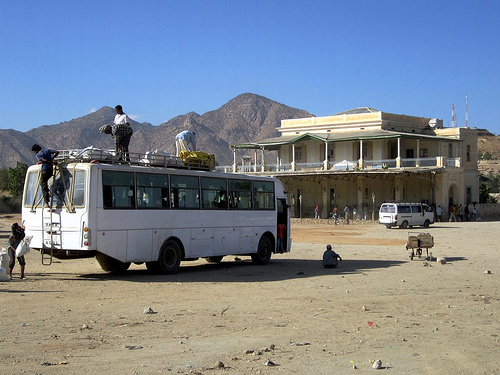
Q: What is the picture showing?
A: It is showing a road.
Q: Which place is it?
A: It is a road.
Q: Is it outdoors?
A: Yes, it is outdoors.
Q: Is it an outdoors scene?
A: Yes, it is outdoors.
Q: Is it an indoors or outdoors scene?
A: It is outdoors.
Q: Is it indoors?
A: No, it is outdoors.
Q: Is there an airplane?
A: No, there are no airplanes.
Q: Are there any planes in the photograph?
A: No, there are no planes.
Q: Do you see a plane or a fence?
A: No, there are no airplanes or fences.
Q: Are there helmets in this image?
A: No, there are no helmets.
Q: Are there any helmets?
A: No, there are no helmets.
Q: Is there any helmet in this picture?
A: No, there are no helmets.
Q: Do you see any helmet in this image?
A: No, there are no helmets.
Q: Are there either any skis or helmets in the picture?
A: No, there are no helmets or skis.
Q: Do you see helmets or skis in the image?
A: No, there are no helmets or skis.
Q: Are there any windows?
A: Yes, there is a window.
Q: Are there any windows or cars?
A: Yes, there is a window.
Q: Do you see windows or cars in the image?
A: Yes, there is a window.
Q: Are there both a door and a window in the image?
A: Yes, there are both a window and a door.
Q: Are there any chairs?
A: No, there are no chairs.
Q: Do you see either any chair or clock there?
A: No, there are no chairs or clocks.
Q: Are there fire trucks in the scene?
A: No, there are no fire trucks.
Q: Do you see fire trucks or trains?
A: No, there are no fire trucks or trains.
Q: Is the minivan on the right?
A: Yes, the minivan is on the right of the image.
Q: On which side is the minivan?
A: The minivan is on the right of the image.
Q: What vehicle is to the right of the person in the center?
A: The vehicle is a minivan.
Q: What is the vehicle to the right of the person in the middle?
A: The vehicle is a minivan.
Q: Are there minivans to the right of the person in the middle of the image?
A: Yes, there is a minivan to the right of the person.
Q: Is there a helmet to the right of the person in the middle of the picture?
A: No, there is a minivan to the right of the person.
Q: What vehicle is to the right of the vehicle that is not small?
A: The vehicle is a minivan.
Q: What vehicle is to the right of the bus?
A: The vehicle is a minivan.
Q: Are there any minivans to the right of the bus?
A: Yes, there is a minivan to the right of the bus.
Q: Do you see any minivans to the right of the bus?
A: Yes, there is a minivan to the right of the bus.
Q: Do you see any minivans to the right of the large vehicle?
A: Yes, there is a minivan to the right of the bus.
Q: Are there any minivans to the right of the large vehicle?
A: Yes, there is a minivan to the right of the bus.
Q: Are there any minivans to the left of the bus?
A: No, the minivan is to the right of the bus.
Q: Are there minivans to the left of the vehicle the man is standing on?
A: No, the minivan is to the right of the bus.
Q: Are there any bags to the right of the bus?
A: No, there is a minivan to the right of the bus.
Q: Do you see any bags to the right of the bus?
A: No, there is a minivan to the right of the bus.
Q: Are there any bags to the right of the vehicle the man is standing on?
A: No, there is a minivan to the right of the bus.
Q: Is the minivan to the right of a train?
A: No, the minivan is to the right of a bus.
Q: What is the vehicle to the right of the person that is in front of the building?
A: The vehicle is a minivan.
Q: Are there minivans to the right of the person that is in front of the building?
A: Yes, there is a minivan to the right of the person.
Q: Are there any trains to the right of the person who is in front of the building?
A: No, there is a minivan to the right of the person.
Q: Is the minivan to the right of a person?
A: Yes, the minivan is to the right of a person.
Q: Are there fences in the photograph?
A: No, there are no fences.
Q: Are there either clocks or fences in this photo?
A: No, there are no fences or clocks.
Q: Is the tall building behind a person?
A: Yes, the building is behind a person.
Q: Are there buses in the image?
A: Yes, there is a bus.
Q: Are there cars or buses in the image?
A: Yes, there is a bus.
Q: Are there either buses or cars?
A: Yes, there is a bus.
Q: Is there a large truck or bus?
A: Yes, there is a large bus.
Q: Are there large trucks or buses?
A: Yes, there is a large bus.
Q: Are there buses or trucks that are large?
A: Yes, the bus is large.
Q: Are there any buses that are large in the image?
A: Yes, there is a large bus.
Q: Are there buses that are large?
A: Yes, there is a bus that is large.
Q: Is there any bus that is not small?
A: Yes, there is a large bus.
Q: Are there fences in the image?
A: No, there are no fences.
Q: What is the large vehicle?
A: The vehicle is a bus.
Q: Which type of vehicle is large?
A: The vehicle is a bus.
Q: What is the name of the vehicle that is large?
A: The vehicle is a bus.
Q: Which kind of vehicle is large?
A: The vehicle is a bus.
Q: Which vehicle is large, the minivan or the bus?
A: The bus is large.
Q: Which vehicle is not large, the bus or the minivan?
A: The minivan is not large.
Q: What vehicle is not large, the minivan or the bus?
A: The minivan is not large.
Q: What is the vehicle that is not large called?
A: The vehicle is a minivan.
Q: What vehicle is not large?
A: The vehicle is a minivan.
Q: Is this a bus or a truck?
A: This is a bus.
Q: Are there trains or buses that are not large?
A: No, there is a bus but it is large.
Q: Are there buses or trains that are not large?
A: No, there is a bus but it is large.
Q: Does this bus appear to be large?
A: Yes, the bus is large.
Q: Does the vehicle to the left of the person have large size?
A: Yes, the bus is large.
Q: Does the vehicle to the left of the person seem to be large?
A: Yes, the bus is large.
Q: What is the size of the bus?
A: The bus is large.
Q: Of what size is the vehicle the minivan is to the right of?
A: The bus is large.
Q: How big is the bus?
A: The bus is large.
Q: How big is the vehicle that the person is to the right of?
A: The bus is large.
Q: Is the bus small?
A: No, the bus is large.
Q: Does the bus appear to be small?
A: No, the bus is large.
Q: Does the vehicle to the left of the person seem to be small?
A: No, the bus is large.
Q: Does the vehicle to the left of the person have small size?
A: No, the bus is large.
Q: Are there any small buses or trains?
A: No, there is a bus but it is large.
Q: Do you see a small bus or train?
A: No, there is a bus but it is large.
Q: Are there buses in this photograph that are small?
A: No, there is a bus but it is large.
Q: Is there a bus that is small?
A: No, there is a bus but it is large.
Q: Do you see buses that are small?
A: No, there is a bus but it is large.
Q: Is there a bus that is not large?
A: No, there is a bus but it is large.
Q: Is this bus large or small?
A: The bus is large.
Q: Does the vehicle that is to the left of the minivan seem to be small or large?
A: The bus is large.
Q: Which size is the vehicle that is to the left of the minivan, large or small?
A: The bus is large.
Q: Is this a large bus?
A: Yes, this is a large bus.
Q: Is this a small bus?
A: No, this is a large bus.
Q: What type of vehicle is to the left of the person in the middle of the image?
A: The vehicle is a bus.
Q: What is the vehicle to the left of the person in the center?
A: The vehicle is a bus.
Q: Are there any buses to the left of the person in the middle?
A: Yes, there is a bus to the left of the person.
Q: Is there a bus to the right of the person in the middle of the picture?
A: No, the bus is to the left of the person.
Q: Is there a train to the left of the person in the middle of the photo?
A: No, there is a bus to the left of the person.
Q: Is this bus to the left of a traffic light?
A: No, the bus is to the left of a person.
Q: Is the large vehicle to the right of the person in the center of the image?
A: No, the bus is to the left of the person.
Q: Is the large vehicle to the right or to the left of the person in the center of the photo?
A: The bus is to the left of the person.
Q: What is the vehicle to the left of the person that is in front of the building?
A: The vehicle is a bus.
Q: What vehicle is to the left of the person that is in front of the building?
A: The vehicle is a bus.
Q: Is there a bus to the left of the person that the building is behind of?
A: Yes, there is a bus to the left of the person.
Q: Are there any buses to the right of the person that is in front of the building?
A: No, the bus is to the left of the person.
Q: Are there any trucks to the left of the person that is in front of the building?
A: No, there is a bus to the left of the person.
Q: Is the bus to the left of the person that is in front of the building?
A: Yes, the bus is to the left of the person.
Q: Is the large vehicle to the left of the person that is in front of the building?
A: Yes, the bus is to the left of the person.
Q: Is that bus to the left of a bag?
A: No, the bus is to the left of the person.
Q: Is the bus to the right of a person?
A: No, the bus is to the left of a person.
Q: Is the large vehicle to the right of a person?
A: No, the bus is to the left of a person.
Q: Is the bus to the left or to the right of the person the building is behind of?
A: The bus is to the left of the person.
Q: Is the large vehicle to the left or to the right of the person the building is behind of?
A: The bus is to the left of the person.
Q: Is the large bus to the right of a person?
A: No, the bus is to the left of a person.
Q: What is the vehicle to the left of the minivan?
A: The vehicle is a bus.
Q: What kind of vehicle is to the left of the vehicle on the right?
A: The vehicle is a bus.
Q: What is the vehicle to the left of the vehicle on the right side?
A: The vehicle is a bus.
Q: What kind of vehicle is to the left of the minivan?
A: The vehicle is a bus.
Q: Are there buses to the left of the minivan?
A: Yes, there is a bus to the left of the minivan.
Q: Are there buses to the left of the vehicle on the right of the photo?
A: Yes, there is a bus to the left of the minivan.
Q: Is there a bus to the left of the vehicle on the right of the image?
A: Yes, there is a bus to the left of the minivan.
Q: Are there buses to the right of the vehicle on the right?
A: No, the bus is to the left of the minivan.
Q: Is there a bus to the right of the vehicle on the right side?
A: No, the bus is to the left of the minivan.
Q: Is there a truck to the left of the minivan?
A: No, there is a bus to the left of the minivan.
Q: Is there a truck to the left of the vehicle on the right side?
A: No, there is a bus to the left of the minivan.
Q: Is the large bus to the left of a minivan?
A: Yes, the bus is to the left of a minivan.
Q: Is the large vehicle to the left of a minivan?
A: Yes, the bus is to the left of a minivan.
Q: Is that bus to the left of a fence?
A: No, the bus is to the left of a minivan.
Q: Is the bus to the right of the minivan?
A: No, the bus is to the left of the minivan.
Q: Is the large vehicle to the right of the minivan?
A: No, the bus is to the left of the minivan.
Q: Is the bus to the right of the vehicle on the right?
A: No, the bus is to the left of the minivan.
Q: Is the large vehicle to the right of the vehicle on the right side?
A: No, the bus is to the left of the minivan.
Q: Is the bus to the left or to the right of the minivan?
A: The bus is to the left of the minivan.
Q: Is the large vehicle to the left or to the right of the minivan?
A: The bus is to the left of the minivan.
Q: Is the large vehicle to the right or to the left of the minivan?
A: The bus is to the left of the minivan.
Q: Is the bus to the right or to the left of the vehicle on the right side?
A: The bus is to the left of the minivan.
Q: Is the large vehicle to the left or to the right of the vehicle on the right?
A: The bus is to the left of the minivan.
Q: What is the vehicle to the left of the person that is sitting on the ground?
A: The vehicle is a bus.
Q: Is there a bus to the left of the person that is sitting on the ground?
A: Yes, there is a bus to the left of the person.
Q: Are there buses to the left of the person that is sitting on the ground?
A: Yes, there is a bus to the left of the person.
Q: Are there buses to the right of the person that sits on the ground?
A: No, the bus is to the left of the person.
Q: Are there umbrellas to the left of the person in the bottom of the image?
A: No, there is a bus to the left of the person.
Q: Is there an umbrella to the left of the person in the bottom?
A: No, there is a bus to the left of the person.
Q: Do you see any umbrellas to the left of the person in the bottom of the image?
A: No, there is a bus to the left of the person.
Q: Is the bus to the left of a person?
A: Yes, the bus is to the left of a person.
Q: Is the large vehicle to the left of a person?
A: Yes, the bus is to the left of a person.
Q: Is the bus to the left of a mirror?
A: No, the bus is to the left of a person.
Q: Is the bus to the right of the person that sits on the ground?
A: No, the bus is to the left of the person.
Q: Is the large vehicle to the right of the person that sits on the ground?
A: No, the bus is to the left of the person.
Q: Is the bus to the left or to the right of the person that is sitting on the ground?
A: The bus is to the left of the person.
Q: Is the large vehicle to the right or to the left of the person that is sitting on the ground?
A: The bus is to the left of the person.